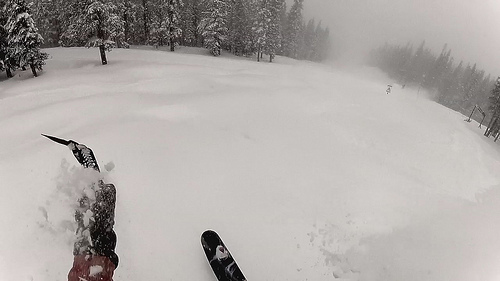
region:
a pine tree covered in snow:
[201, 2, 228, 59]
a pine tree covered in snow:
[74, 4, 121, 66]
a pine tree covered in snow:
[435, 42, 462, 106]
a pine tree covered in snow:
[256, 5, 273, 59]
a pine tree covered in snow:
[4, 2, 49, 74]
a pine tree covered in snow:
[46, 2, 65, 50]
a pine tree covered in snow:
[288, 8, 305, 64]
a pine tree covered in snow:
[308, 22, 324, 68]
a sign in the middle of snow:
[386, 83, 393, 98]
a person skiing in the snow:
[46, 121, 268, 279]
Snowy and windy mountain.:
[1, 2, 487, 269]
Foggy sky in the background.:
[312, 1, 494, 51]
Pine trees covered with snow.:
[7, 5, 497, 117]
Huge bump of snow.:
[120, 65, 465, 255]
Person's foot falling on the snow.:
[66, 170, 124, 276]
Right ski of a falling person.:
[200, 225, 243, 277]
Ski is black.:
[198, 226, 253, 276]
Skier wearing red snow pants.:
[55, 252, 130, 278]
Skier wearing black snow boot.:
[72, 178, 127, 263]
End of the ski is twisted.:
[39, 126, 112, 173]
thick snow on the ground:
[149, 103, 435, 213]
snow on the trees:
[2, 2, 332, 84]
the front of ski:
[200, 227, 247, 279]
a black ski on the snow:
[197, 228, 249, 280]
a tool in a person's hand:
[40, 128, 108, 181]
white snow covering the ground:
[120, 80, 380, 175]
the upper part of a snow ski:
[197, 225, 247, 276]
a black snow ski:
[200, 227, 250, 277]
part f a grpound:
[181, 203, 200, 231]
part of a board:
[206, 234, 219, 263]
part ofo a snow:
[286, 158, 323, 207]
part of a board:
[208, 248, 220, 275]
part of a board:
[210, 238, 226, 265]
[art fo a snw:
[262, 137, 308, 198]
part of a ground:
[216, 108, 266, 175]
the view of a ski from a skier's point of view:
[178, 215, 263, 279]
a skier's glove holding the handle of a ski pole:
[39, 133, 121, 274]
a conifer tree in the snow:
[79, 0, 119, 69]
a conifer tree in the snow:
[3, 8, 44, 85]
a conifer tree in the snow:
[158, 0, 187, 58]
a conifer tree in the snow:
[136, 0, 156, 52]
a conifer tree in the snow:
[204, 0, 227, 62]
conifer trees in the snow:
[247, 0, 277, 66]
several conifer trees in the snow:
[366, 37, 498, 122]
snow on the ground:
[28, 23, 488, 279]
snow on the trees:
[6, 8, 293, 85]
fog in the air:
[268, 3, 480, 123]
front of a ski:
[182, 216, 248, 279]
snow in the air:
[30, 145, 130, 258]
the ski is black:
[186, 222, 257, 279]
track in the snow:
[428, 116, 470, 156]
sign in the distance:
[382, 82, 394, 97]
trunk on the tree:
[95, 46, 112, 68]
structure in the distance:
[463, 97, 486, 130]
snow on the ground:
[26, 42, 490, 268]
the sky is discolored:
[303, 5, 497, 74]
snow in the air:
[25, 145, 125, 242]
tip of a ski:
[186, 230, 246, 278]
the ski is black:
[188, 216, 244, 279]